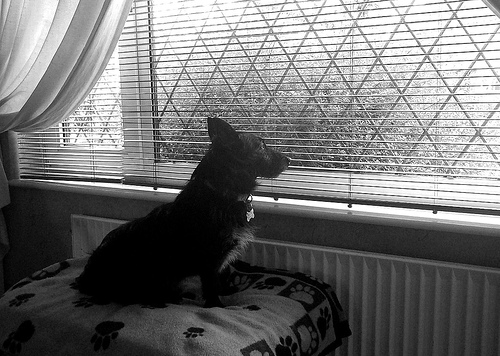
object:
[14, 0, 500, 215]
blinds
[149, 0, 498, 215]
window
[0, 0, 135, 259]
curtain